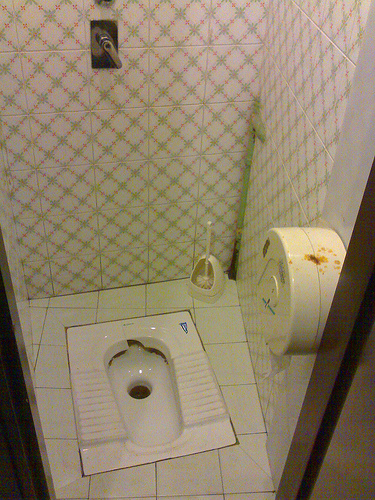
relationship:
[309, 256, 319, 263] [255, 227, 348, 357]
speck on frame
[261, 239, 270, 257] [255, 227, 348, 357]
hole in frame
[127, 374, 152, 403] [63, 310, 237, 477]
hole in toilet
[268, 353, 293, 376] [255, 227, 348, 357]
paper coming out of frame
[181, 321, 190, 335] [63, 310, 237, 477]
symbol on toilet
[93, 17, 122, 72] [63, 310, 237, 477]
handle for toilet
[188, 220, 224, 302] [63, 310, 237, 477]
cleaner for toilet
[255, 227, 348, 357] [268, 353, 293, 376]
frame for paper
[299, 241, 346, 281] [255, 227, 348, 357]
scum on frame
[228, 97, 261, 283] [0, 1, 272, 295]
pole against wall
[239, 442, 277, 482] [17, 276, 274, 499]
crack in tile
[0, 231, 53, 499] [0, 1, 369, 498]
part of doorway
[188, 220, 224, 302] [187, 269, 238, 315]
cleaner in corner